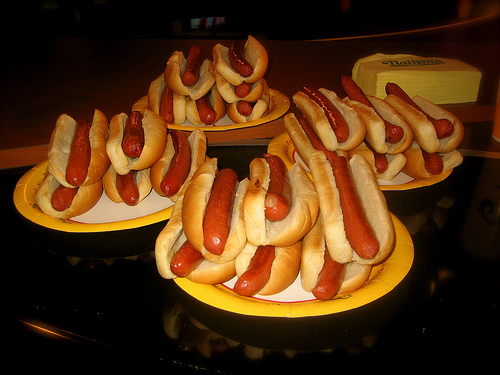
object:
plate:
[172, 210, 414, 318]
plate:
[132, 88, 291, 131]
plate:
[13, 156, 212, 234]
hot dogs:
[147, 35, 267, 125]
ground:
[0, 358, 500, 374]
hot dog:
[35, 108, 212, 218]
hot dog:
[283, 74, 463, 181]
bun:
[308, 151, 395, 265]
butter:
[350, 53, 483, 105]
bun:
[181, 157, 247, 263]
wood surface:
[25, 39, 498, 181]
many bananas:
[351, 53, 481, 106]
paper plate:
[266, 130, 453, 191]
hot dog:
[155, 150, 395, 300]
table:
[7, 168, 497, 371]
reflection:
[162, 301, 369, 358]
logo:
[380, 58, 447, 67]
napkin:
[352, 53, 482, 105]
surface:
[0, 140, 498, 373]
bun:
[243, 153, 320, 247]